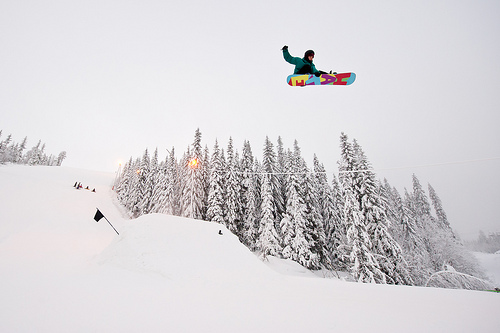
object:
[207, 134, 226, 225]
tree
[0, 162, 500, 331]
mountainside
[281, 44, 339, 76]
person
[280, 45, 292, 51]
glove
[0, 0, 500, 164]
clouds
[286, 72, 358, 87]
bottom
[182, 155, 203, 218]
light pole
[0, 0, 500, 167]
sky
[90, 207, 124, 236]
flag marker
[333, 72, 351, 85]
letter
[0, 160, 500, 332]
ski slope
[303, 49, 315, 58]
helmet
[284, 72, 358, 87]
snowboard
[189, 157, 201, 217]
light